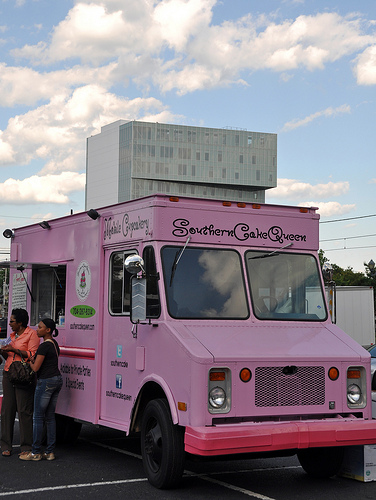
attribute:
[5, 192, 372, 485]
truck — two-toned pink, pink colored, pink in color, painted pink, light pink, pink, a van, cake truck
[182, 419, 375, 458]
bumper — dark pink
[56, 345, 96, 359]
stripe — dark pink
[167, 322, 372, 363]
hood — pink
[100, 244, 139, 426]
door — pink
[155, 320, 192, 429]
fender — pink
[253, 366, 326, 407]
grille — pink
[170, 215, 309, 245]
writing — company name, black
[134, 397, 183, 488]
tire — black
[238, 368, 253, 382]
turn signal — orange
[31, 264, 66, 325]
window — open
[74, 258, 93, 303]
logo — here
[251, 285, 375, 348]
building — white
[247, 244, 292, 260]
windshield wiper — black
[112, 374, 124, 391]
facebook logo — printed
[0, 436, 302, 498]
lines — white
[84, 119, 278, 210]
building — tall